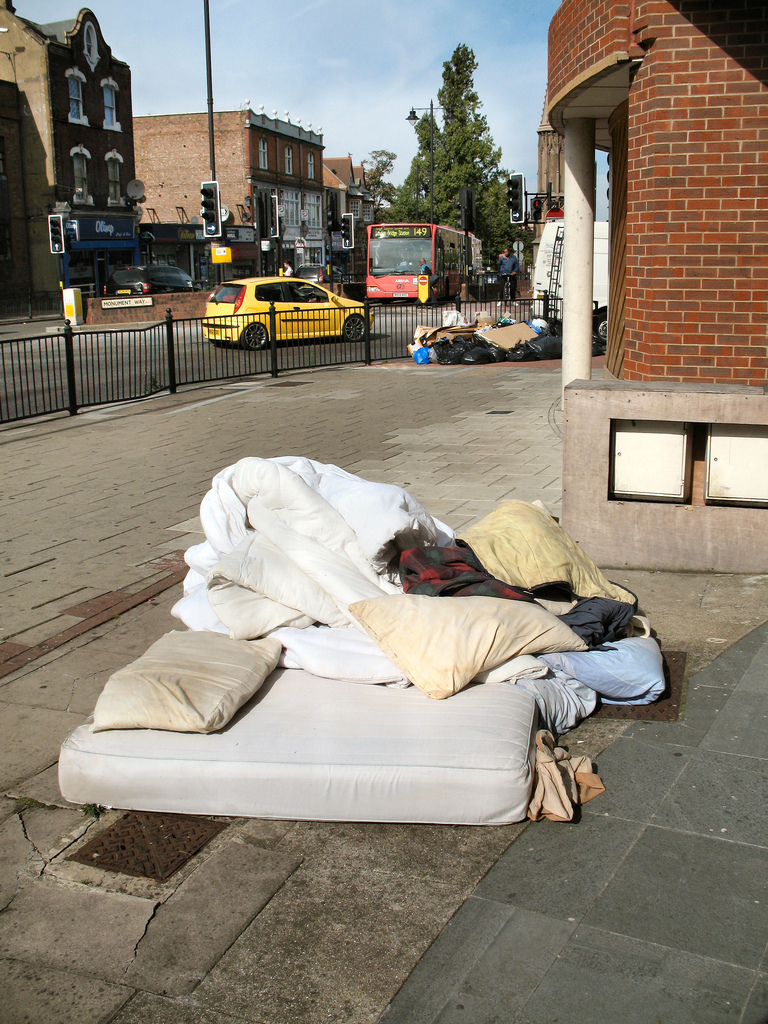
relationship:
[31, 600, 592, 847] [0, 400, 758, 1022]
mattress on street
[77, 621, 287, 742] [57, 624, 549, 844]
pillow on mattress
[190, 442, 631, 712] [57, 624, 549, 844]
blankets on mattress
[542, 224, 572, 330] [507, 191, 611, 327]
ladder on van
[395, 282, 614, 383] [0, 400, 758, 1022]
garbage on street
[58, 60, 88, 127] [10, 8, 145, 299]
window on building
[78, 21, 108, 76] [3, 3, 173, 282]
window on building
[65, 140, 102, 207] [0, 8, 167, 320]
window on building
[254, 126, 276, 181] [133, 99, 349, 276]
window on building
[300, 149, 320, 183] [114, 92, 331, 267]
window on building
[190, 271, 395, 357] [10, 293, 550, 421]
car on street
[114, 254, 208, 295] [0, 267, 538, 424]
car on street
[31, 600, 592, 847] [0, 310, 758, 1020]
mattress on street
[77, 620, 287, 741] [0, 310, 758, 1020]
pillow on street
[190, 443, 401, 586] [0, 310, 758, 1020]
blankets on street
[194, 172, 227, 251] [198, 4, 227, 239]
street light on pole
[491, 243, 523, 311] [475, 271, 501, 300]
man in shirt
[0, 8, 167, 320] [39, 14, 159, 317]
building has store front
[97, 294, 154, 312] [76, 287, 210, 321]
sign on wall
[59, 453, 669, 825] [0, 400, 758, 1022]
trash littering street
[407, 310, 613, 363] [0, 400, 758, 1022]
garbage piling up street